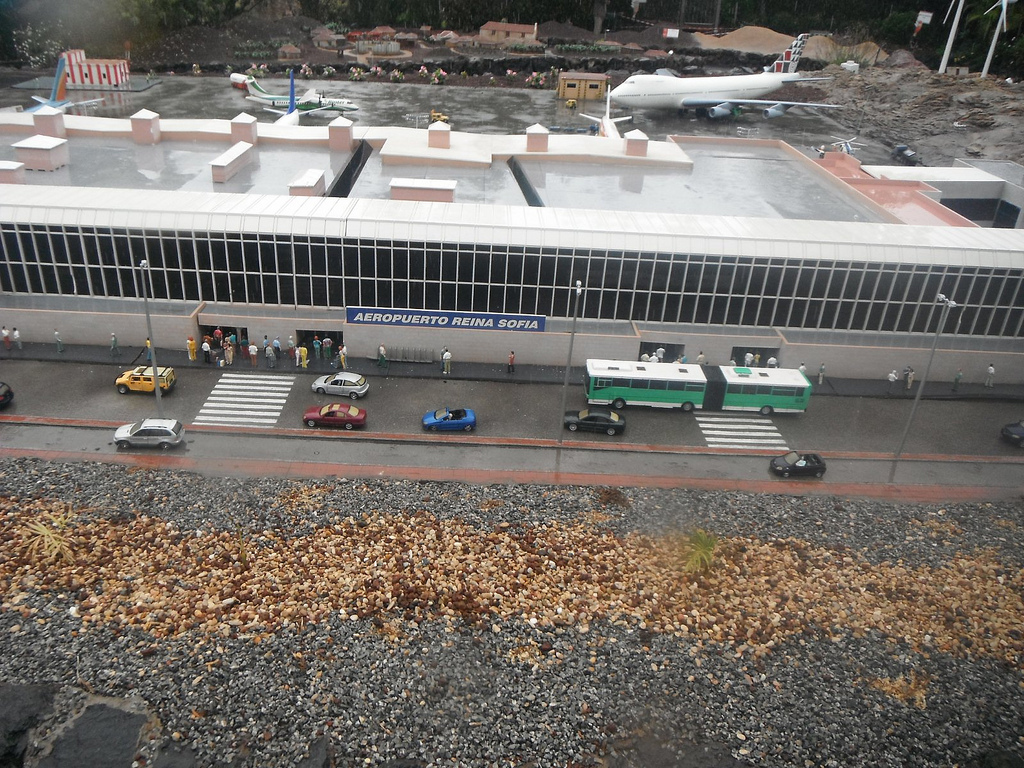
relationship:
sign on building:
[340, 305, 552, 336] [1, 99, 1023, 385]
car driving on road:
[770, 450, 827, 477] [1, 415, 1021, 495]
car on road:
[421, 406, 476, 431] [9, 354, 1021, 506]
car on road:
[302, 403, 367, 430] [9, 354, 1021, 506]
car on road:
[115, 364, 176, 394] [9, 354, 1021, 506]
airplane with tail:
[610, 34, 845, 121] [757, 31, 814, 73]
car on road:
[560, 410, 634, 447] [9, 354, 1021, 506]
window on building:
[657, 261, 683, 294] [1, 99, 1023, 385]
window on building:
[653, 254, 693, 302] [1, 99, 1023, 385]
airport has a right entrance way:
[28, 48, 977, 383] [293, 322, 350, 379]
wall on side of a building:
[170, 290, 706, 409] [47, 147, 916, 515]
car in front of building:
[115, 364, 176, 394] [1, 99, 1023, 385]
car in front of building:
[113, 418, 185, 449] [1, 99, 1023, 385]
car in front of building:
[308, 371, 375, 395] [1, 99, 1023, 385]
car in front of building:
[297, 399, 378, 438] [1, 99, 1023, 385]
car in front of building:
[418, 399, 481, 439] [1, 99, 1023, 385]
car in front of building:
[562, 409, 625, 436] [1, 99, 1023, 385]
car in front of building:
[770, 442, 831, 482] [1, 99, 1023, 385]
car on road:
[418, 399, 481, 439] [0, 340, 1024, 491]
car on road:
[109, 360, 174, 400] [0, 340, 1024, 491]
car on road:
[109, 412, 190, 454] [0, 340, 1024, 491]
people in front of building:
[182, 328, 351, 367] [1, 99, 1023, 385]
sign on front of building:
[343, 307, 545, 334] [1, 99, 1023, 385]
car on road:
[562, 409, 625, 436] [0, 340, 1024, 491]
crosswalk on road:
[191, 367, 298, 434] [0, 340, 1024, 491]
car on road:
[421, 406, 476, 431] [0, 340, 1024, 491]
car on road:
[115, 364, 176, 394] [0, 340, 1024, 491]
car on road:
[310, 371, 368, 401] [0, 340, 1024, 491]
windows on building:
[5, 220, 1023, 341] [1, 99, 1023, 385]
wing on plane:
[682, 94, 842, 114] [608, 30, 844, 121]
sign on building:
[343, 307, 545, 334] [1, 99, 1023, 385]